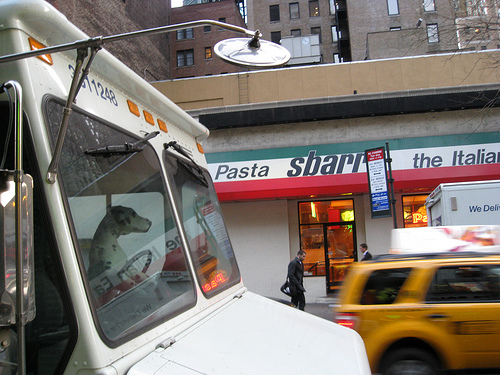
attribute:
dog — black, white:
[90, 204, 160, 319]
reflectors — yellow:
[125, 96, 167, 132]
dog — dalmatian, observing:
[76, 194, 161, 245]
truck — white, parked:
[6, 5, 342, 374]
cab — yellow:
[332, 236, 483, 366]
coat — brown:
[285, 262, 309, 290]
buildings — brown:
[172, 4, 483, 58]